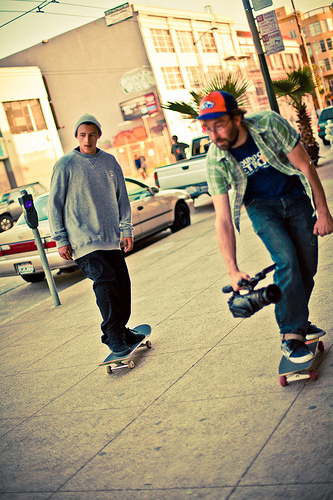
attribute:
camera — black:
[218, 262, 287, 319]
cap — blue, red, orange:
[194, 93, 245, 120]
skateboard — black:
[100, 322, 162, 374]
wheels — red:
[278, 338, 327, 388]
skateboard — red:
[279, 338, 326, 387]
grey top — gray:
[45, 145, 135, 261]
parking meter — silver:
[16, 189, 66, 309]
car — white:
[0, 177, 196, 283]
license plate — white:
[16, 264, 34, 276]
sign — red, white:
[255, 10, 289, 57]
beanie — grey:
[72, 114, 102, 139]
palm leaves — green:
[267, 68, 320, 109]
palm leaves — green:
[160, 71, 252, 120]